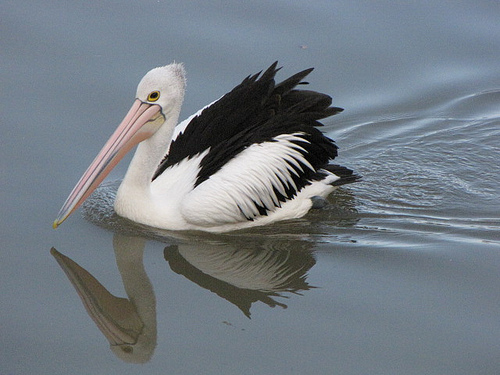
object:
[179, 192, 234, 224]
white feathers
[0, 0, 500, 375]
water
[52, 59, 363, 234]
bird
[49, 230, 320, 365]
reflection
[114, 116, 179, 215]
neck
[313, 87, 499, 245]
wave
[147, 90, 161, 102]
eye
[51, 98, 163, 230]
beak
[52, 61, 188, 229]
head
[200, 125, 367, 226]
wind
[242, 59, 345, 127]
bird tail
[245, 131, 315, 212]
feather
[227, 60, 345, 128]
black feathers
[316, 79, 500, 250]
ripple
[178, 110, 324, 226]
wing